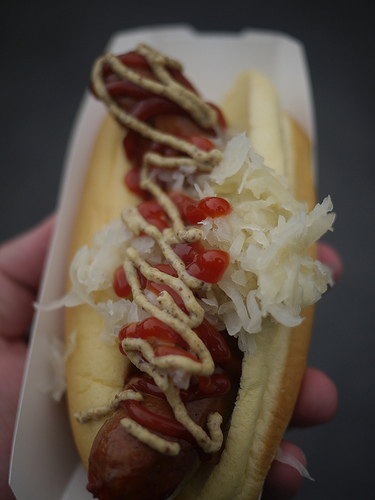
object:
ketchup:
[122, 132, 218, 198]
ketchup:
[134, 189, 233, 233]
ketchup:
[109, 238, 230, 302]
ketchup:
[116, 314, 235, 395]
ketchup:
[124, 396, 194, 448]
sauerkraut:
[207, 133, 252, 186]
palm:
[0, 264, 44, 498]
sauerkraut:
[32, 294, 70, 315]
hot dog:
[31, 44, 336, 499]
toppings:
[30, 42, 334, 459]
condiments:
[177, 284, 185, 295]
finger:
[289, 371, 339, 431]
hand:
[0, 204, 342, 500]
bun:
[178, 71, 315, 499]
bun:
[60, 118, 136, 476]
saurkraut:
[217, 274, 263, 336]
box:
[6, 26, 321, 498]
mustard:
[122, 238, 206, 330]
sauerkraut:
[275, 442, 312, 484]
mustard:
[71, 386, 141, 425]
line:
[119, 413, 182, 459]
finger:
[268, 435, 307, 487]